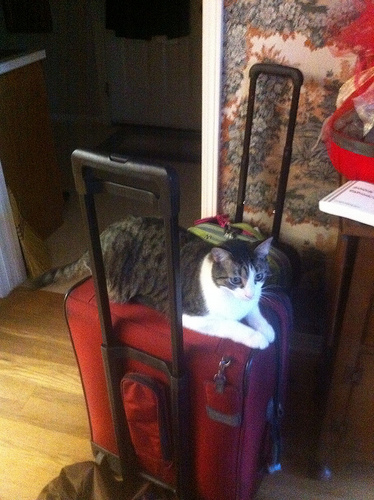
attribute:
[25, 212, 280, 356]
cat — dark, ready, tabby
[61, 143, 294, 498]
suitcase — red, upright, pull along, indicating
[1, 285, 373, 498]
floor — brown, carpeted, wooden, wood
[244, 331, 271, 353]
paw — white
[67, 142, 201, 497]
handle — telescoping, black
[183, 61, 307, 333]
suitcase — green, light green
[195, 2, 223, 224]
door frame — white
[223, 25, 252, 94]
flower — blue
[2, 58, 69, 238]
cabinet — wooden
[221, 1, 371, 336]
wallpaper — gray, patterned, floral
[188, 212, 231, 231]
tag — red, identification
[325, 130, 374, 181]
bowl — red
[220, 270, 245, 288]
eye — almond-shaped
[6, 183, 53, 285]
broom — straw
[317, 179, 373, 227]
book — white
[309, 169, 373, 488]
table — antique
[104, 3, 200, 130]
door — white